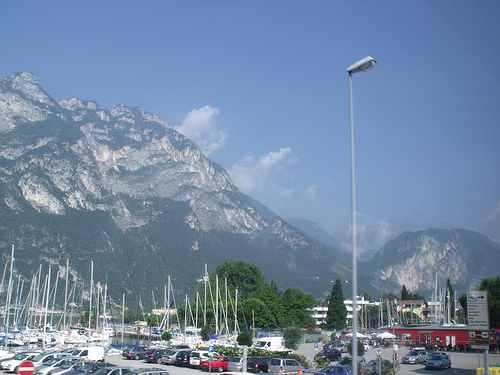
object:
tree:
[323, 277, 350, 332]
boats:
[4, 244, 112, 344]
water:
[112, 330, 151, 352]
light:
[344, 56, 378, 375]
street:
[243, 307, 500, 351]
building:
[383, 324, 483, 349]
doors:
[445, 335, 458, 348]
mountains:
[0, 85, 218, 209]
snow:
[0, 72, 271, 235]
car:
[203, 354, 230, 371]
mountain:
[0, 75, 500, 319]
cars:
[110, 338, 453, 372]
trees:
[164, 258, 350, 367]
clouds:
[164, 94, 311, 191]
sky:
[0, 0, 500, 257]